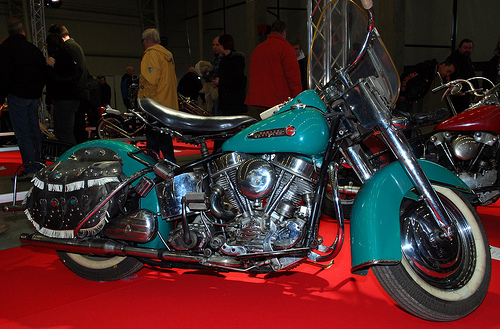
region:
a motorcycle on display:
[32, 53, 493, 299]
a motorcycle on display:
[26, 47, 456, 327]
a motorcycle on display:
[25, 30, 476, 298]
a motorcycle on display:
[17, 11, 430, 327]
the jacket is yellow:
[128, 45, 179, 110]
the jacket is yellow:
[129, 40, 177, 114]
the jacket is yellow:
[129, 44, 179, 126]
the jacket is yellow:
[133, 42, 178, 124]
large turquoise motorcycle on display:
[8, 30, 498, 320]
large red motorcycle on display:
[400, 50, 492, 221]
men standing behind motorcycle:
[7, 8, 323, 149]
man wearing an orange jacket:
[247, 30, 314, 126]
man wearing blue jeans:
[2, 90, 69, 187]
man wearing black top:
[7, 32, 55, 107]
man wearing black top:
[47, 39, 97, 116]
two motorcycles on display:
[28, 69, 496, 314]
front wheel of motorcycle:
[355, 146, 490, 324]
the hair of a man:
[132, 21, 174, 55]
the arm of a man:
[134, 39, 172, 90]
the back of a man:
[241, 15, 303, 99]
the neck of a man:
[211, 35, 243, 72]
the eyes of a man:
[200, 21, 239, 111]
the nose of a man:
[204, 22, 244, 62]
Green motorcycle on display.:
[17, 15, 498, 317]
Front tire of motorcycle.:
[346, 155, 488, 320]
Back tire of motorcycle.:
[43, 132, 162, 282]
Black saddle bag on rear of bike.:
[19, 150, 129, 234]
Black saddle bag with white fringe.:
[24, 158, 129, 239]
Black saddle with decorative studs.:
[22, 150, 125, 239]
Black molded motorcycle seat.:
[137, 85, 252, 140]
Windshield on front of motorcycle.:
[330, 5, 401, 115]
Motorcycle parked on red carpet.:
[0, 50, 495, 326]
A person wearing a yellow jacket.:
[126, 29, 185, 117]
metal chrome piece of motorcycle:
[324, 165, 347, 268]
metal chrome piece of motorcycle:
[267, 168, 286, 213]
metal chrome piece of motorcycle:
[262, 173, 296, 220]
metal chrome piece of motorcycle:
[237, 245, 305, 263]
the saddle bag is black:
[19, 155, 124, 240]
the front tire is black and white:
[371, 182, 491, 323]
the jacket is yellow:
[137, 44, 178, 109]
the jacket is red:
[243, 32, 300, 109]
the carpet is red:
[3, 199, 498, 326]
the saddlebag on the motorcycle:
[20, 0, 493, 320]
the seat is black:
[136, 95, 256, 140]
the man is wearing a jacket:
[137, 25, 177, 110]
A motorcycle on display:
[15, 8, 494, 325]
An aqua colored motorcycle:
[12, 34, 499, 316]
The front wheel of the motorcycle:
[348, 152, 493, 318]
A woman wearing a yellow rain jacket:
[129, 20, 186, 115]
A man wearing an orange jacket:
[246, 19, 303, 108]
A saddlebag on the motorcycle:
[15, 154, 127, 245]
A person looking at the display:
[40, 16, 97, 141]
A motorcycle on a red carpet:
[20, 27, 490, 321]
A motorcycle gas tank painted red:
[435, 99, 498, 131]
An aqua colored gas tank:
[216, 87, 334, 163]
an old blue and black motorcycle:
[28, 70, 490, 315]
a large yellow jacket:
[137, 46, 179, 107]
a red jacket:
[243, 28, 303, 103]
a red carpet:
[0, 220, 499, 327]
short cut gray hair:
[138, 26, 163, 45]